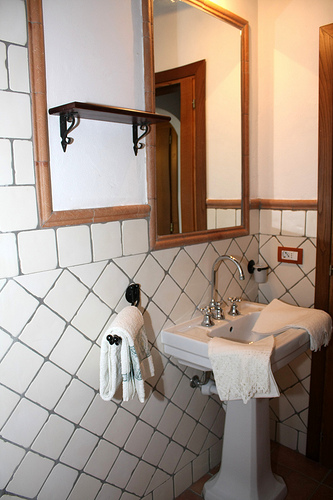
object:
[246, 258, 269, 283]
cup holder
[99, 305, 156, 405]
towel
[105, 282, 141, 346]
rack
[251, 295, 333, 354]
towel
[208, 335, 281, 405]
towel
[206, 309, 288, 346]
basin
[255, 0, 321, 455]
wall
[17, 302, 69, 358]
tile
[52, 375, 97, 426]
tile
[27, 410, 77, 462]
tile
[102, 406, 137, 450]
tile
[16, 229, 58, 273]
tile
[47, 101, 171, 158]
shelf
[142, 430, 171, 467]
tiles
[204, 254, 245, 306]
faucet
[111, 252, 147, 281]
tile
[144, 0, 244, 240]
mirror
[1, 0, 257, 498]
wall